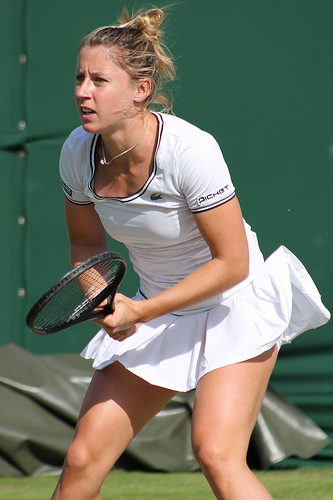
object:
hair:
[78, 5, 179, 108]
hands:
[92, 294, 138, 338]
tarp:
[2, 344, 328, 477]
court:
[0, 455, 333, 499]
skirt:
[75, 244, 331, 393]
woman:
[26, 9, 331, 498]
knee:
[62, 439, 94, 469]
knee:
[193, 442, 229, 472]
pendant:
[98, 156, 107, 165]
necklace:
[92, 111, 151, 167]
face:
[73, 43, 132, 136]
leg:
[189, 346, 282, 498]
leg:
[49, 363, 174, 498]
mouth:
[78, 103, 100, 119]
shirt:
[58, 108, 266, 319]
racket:
[24, 249, 122, 336]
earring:
[133, 96, 145, 101]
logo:
[146, 190, 167, 205]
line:
[85, 106, 166, 209]